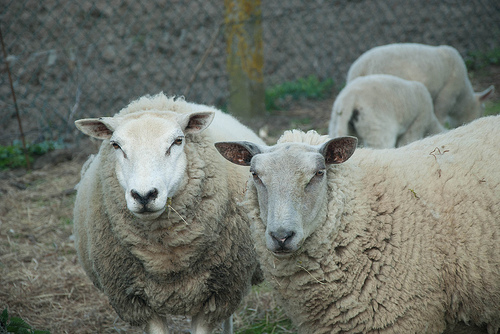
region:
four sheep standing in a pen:
[70, 32, 481, 324]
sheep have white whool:
[69, 96, 338, 296]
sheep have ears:
[209, 124, 365, 179]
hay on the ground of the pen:
[5, 174, 98, 331]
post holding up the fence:
[216, 8, 289, 116]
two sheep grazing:
[304, 21, 496, 171]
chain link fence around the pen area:
[22, 11, 230, 84]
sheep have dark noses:
[124, 183, 305, 261]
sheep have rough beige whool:
[121, 188, 460, 303]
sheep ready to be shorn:
[69, 93, 494, 323]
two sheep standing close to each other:
[51, 98, 496, 308]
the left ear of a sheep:
[322, 130, 358, 163]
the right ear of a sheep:
[215, 140, 260, 170]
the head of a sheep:
[223, 123, 350, 255]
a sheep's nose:
[266, 220, 296, 247]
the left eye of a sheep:
[311, 163, 328, 181]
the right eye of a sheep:
[248, 165, 263, 184]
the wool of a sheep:
[105, 224, 214, 271]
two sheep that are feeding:
[335, 36, 491, 140]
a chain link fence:
[44, 1, 223, 92]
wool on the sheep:
[382, 220, 427, 253]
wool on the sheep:
[394, 252, 423, 263]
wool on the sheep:
[382, 279, 407, 306]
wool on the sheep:
[152, 270, 181, 295]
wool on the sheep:
[437, 185, 481, 226]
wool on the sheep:
[415, 168, 460, 202]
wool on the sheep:
[149, 271, 186, 308]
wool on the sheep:
[210, 186, 232, 228]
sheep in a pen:
[36, 20, 492, 309]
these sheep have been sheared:
[313, 37, 480, 135]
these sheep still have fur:
[47, 119, 497, 316]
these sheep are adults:
[52, 99, 346, 284]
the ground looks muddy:
[5, 165, 92, 327]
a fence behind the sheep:
[9, 8, 324, 121]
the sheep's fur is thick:
[77, 124, 497, 318]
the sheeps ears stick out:
[72, 113, 365, 185]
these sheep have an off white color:
[59, 112, 499, 327]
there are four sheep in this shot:
[95, 32, 490, 311]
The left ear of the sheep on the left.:
[72, 118, 117, 138]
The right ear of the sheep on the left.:
[189, 110, 214, 131]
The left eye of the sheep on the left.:
[110, 137, 118, 152]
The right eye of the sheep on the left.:
[175, 136, 180, 146]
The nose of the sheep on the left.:
[134, 189, 158, 201]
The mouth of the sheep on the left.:
[122, 206, 166, 216]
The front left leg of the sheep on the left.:
[145, 314, 164, 331]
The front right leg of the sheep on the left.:
[192, 314, 212, 332]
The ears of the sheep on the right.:
[212, 133, 358, 169]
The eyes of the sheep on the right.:
[246, 166, 331, 182]